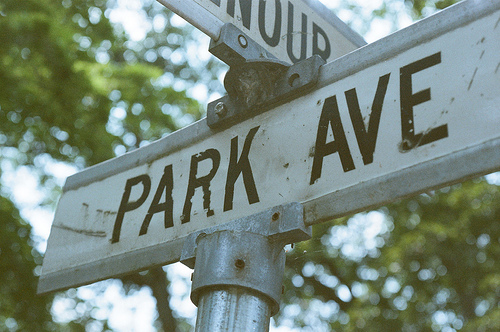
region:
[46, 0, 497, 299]
this is a sign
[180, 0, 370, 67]
this is a sign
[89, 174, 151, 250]
a letter on the sign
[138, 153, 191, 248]
a letter on the sign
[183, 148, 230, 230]
a letter on the sign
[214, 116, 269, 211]
a letter on the sign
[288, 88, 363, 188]
a letter on the sign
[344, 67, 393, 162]
a letter on the sign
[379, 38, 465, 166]
a letter on the sign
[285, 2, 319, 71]
a letter on the sign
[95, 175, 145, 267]
Black letter on white sign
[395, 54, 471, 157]
Black letter on white sign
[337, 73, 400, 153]
Black letter on white sign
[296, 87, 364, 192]
Black letter on white sign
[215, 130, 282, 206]
Black letter on white sign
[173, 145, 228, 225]
Black letter on white sign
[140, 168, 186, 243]
Black letter on white sign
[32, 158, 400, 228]
Black and white sign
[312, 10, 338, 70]
Black letter on white sign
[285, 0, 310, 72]
Black letter on white sign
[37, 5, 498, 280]
park ave white signboard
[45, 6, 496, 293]
two signboards on gray pole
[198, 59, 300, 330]
gray metal pole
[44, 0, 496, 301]
gray and white signboard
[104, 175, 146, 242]
P black letter on white signboard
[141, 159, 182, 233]
A black letter on white signboard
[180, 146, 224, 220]
R black letter on white signboard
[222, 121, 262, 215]
K black letter on white signboard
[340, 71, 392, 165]
V black letter on white signboard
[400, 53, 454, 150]
E black letter on white signboard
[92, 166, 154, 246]
The letter is black.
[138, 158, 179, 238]
The letter is black.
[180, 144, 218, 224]
The letter is black.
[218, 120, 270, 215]
The letter is black.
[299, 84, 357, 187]
The letter is black.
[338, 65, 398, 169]
The letter is black.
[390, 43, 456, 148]
The letter is black.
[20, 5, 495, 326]
The sign is black and white.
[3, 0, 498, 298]
The sign is dirty.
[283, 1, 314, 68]
The letter is black.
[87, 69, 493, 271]
street signs on a pole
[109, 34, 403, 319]
signs on a pole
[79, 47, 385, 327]
street signs on a metal pole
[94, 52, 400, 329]
signs on a metal pole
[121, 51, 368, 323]
a pole with street signs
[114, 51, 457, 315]
a metal pole with street signs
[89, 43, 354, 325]
a silver pole with signs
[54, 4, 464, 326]
a silver metal pole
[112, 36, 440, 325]
a silver metal pole with signs